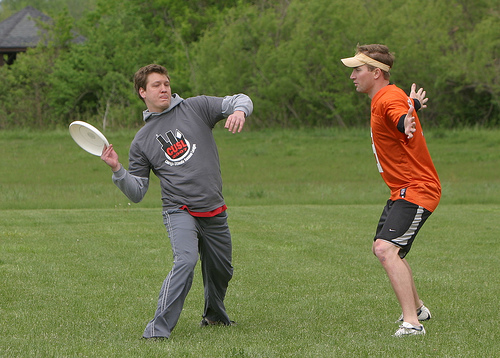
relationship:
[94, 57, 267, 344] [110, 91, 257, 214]
man in sweater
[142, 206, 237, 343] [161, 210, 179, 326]
pants have stripe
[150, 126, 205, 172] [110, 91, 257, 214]
logo on sweater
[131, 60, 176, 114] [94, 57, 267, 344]
head of man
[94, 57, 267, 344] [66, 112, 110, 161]
man throwing frisbee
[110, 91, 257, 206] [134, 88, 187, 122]
sweater has hood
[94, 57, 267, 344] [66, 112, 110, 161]
man tossing frisbee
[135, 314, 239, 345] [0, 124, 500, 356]
feet in grass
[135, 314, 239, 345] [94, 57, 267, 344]
feet of man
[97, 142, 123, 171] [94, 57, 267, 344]
right hand of man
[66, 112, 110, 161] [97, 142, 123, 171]
frisbee in right hand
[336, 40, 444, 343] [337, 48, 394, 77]
man wearing visor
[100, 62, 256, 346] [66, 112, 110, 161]
man playing frisbee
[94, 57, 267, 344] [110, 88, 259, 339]
man in sweatsuit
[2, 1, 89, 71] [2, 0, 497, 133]
structure behind trees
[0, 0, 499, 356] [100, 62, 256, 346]
picture of two man